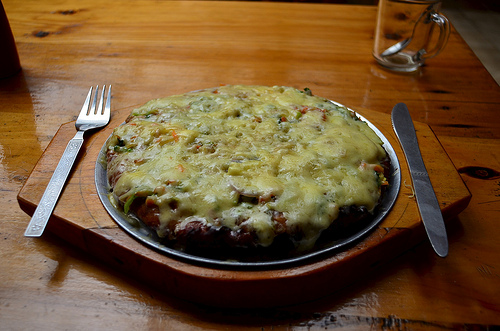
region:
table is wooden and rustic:
[334, 242, 452, 327]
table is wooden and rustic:
[391, 110, 478, 312]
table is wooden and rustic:
[37, 211, 461, 328]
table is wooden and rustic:
[22, 111, 266, 243]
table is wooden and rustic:
[63, 75, 377, 310]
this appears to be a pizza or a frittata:
[96, 69, 428, 284]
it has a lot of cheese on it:
[113, 20, 428, 325]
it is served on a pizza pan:
[91, 82, 404, 277]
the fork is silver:
[3, 77, 140, 284]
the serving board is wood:
[12, 44, 495, 309]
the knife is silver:
[362, 77, 492, 268]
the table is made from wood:
[153, 18, 244, 60]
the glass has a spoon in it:
[371, 2, 458, 82]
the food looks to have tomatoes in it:
[100, 88, 413, 291]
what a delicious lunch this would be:
[91, 73, 428, 295]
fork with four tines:
[20, 61, 127, 276]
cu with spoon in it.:
[370, 2, 456, 77]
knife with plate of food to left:
[337, 80, 484, 291]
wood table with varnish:
[128, 11, 324, 61]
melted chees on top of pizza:
[183, 115, 287, 193]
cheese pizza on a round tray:
[93, 67, 408, 285]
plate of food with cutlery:
[30, 72, 474, 295]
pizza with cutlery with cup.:
[13, 2, 482, 277]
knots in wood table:
[405, 76, 495, 202]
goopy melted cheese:
[243, 104, 306, 149]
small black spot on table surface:
[10, 15, 75, 50]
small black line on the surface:
[343, 305, 422, 325]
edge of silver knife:
[390, 104, 414, 121]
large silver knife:
[385, 75, 445, 276]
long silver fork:
[53, 50, 90, 269]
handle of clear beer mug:
[417, 4, 457, 69]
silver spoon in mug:
[372, 5, 436, 75]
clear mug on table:
[357, 2, 451, 107]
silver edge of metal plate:
[78, 132, 123, 228]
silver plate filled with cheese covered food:
[98, 80, 412, 272]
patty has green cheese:
[127, 127, 291, 227]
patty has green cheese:
[179, 119, 240, 166]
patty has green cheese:
[163, 142, 229, 195]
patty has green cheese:
[177, 96, 323, 218]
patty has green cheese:
[172, 117, 286, 184]